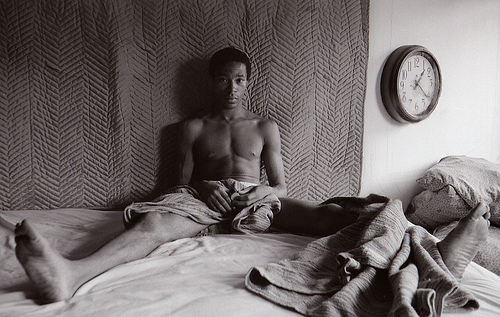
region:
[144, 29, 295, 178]
young boy sits on a bed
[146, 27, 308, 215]
boy has balck hair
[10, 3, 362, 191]
a piece of fabric hangs from a wall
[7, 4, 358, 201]
a piece of fabric behind boy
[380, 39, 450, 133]
a white clock on a wall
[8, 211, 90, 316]
right feet of boy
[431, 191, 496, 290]
left feet of boy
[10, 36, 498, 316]
boy has long feet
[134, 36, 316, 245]
man has a cloth over his lap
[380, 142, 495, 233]
two pillows on the side of room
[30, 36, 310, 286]
Shirtless man on bed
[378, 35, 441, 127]
Clock on wall beside bed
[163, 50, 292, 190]
Boy is shirtless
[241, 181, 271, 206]
Boy's left hand is brown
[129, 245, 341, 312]
Bedsheets on the mattress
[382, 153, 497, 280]
Blankets pushed off to side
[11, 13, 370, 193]
Back of bed is patterned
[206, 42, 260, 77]
Boy has short black hair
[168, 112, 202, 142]
Boy's right shoulder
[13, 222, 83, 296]
Bottom of boy's right foot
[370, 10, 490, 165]
wall under clock is white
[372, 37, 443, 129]
clock has a brown frame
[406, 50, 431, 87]
hour hand is in one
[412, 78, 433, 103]
minute hand is in four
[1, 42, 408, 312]
a man sits on a bed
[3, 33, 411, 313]
a man has legs extended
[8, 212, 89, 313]
bare foot of man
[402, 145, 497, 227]
two pillows under a clock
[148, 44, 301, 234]
color guy has hands on front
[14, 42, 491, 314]
a man sitting on a bed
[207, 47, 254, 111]
the face of a man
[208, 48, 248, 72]
the black hair of a man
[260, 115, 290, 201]
the arm of a man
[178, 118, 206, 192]
the arm of a man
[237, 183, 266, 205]
the hand of a man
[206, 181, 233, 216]
the hand of a man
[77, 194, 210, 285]
the leg of a man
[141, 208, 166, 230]
the knee of a man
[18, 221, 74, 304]
the foot of a man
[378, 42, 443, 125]
clock on the wall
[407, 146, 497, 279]
pile of pillows next to the bed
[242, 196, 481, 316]
blanket at the foot of the bed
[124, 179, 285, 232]
blanket on the man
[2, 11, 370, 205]
blanket hanging on the wall behind the bed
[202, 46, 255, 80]
black hair on the man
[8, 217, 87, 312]
the man's bare foot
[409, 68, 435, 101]
the hands of the clock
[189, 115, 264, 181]
the man's chest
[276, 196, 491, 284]
the man's leg hiding under a blanket